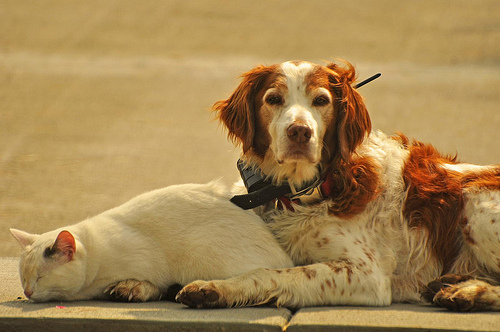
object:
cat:
[7, 175, 304, 307]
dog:
[99, 54, 499, 325]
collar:
[227, 160, 349, 213]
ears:
[219, 55, 260, 157]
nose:
[282, 112, 318, 147]